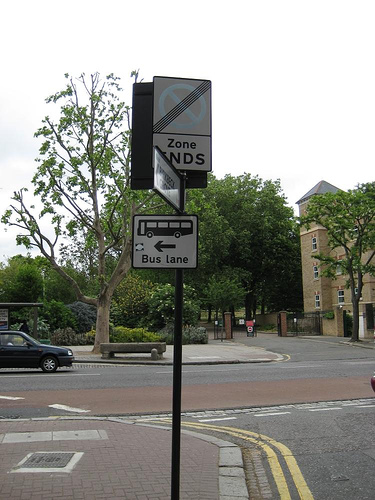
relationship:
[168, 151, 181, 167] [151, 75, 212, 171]
letter on sign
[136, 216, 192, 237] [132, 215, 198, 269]
bus on sign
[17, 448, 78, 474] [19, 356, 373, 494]
metal cover in road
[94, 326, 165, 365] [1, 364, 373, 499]
stone bench on road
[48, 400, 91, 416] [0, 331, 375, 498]
white line on road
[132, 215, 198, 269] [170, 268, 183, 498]
sign on pole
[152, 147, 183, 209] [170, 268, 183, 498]
sign on pole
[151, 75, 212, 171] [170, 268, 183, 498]
sign on pole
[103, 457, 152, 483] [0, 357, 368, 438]
red bricks near road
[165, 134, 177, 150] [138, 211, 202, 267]
letter on sign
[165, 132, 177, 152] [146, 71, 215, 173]
black letter on sign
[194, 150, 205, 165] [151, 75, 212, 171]
letter on sign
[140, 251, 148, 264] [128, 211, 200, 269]
black letter on sign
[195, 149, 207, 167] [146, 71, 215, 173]
black letter on sign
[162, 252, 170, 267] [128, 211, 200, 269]
black letter on sign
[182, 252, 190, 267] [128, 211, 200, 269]
black letter on sign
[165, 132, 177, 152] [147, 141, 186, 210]
black letter on sign